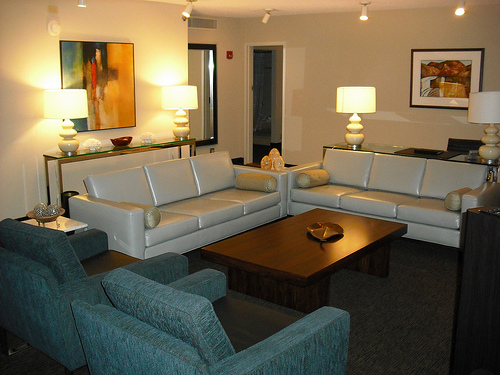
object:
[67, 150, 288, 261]
couch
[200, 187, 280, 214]
cushion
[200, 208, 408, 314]
table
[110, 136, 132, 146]
bowl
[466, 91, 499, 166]
lamp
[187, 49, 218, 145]
mirror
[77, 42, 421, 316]
area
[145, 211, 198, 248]
cushion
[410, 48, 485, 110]
black frame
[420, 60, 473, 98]
art piece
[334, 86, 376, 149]
lamp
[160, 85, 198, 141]
lamp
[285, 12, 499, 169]
white walls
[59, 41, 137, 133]
picture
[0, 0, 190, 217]
wall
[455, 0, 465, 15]
light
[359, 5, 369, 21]
light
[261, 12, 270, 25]
light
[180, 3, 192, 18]
light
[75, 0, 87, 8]
light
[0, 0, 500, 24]
ceiling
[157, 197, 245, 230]
cushion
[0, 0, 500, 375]
light room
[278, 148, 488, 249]
couch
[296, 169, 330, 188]
pillow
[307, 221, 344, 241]
tray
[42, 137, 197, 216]
stand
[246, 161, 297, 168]
table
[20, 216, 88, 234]
table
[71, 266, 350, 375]
blue chair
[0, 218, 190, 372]
blue chair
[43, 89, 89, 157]
lamp